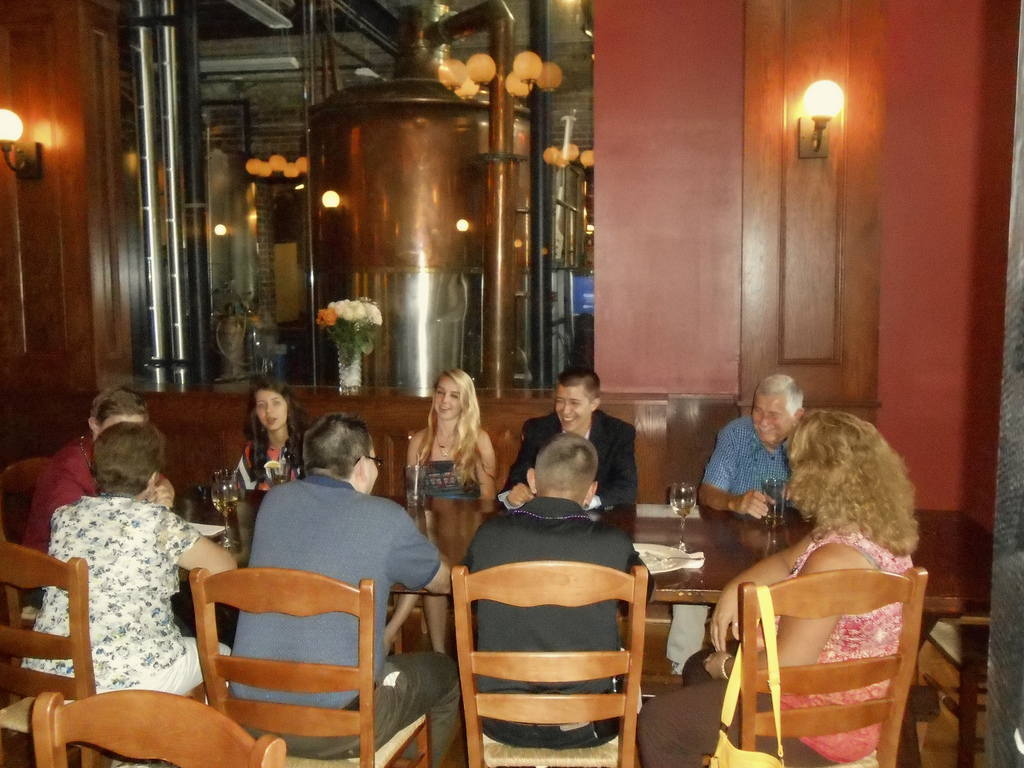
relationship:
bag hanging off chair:
[708, 584, 785, 768] [721, 541, 934, 761]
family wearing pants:
[228, 413, 459, 767] [238, 639, 457, 764]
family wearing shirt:
[228, 413, 459, 767] [229, 467, 445, 718]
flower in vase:
[358, 302, 384, 331] [336, 345, 365, 393]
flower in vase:
[316, 307, 338, 325] [336, 345, 365, 393]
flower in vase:
[339, 300, 365, 330] [336, 345, 365, 393]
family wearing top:
[637, 408, 921, 768] [770, 525, 927, 757]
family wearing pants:
[637, 408, 921, 768] [633, 679, 817, 765]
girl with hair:
[383, 369, 496, 657] [408, 366, 479, 499]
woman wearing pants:
[21, 421, 238, 706] [131, 635, 227, 706]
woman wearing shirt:
[21, 421, 238, 706] [26, 495, 195, 686]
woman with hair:
[222, 381, 325, 506] [244, 381, 306, 476]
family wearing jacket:
[458, 432, 657, 750] [458, 496, 655, 696]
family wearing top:
[637, 408, 921, 768] [772, 524, 913, 758]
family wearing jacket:
[496, 366, 639, 511] [509, 407, 636, 506]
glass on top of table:
[669, 483, 701, 548] [21, 506, 999, 759]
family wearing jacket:
[458, 432, 657, 750] [453, 495, 651, 704]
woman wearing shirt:
[24, 411, 240, 702] [38, 490, 201, 697]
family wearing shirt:
[666, 374, 804, 675] [708, 414, 795, 504]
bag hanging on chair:
[713, 577, 786, 767] [740, 568, 933, 761]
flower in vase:
[315, 306, 341, 330] [329, 331, 365, 401]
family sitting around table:
[231, 410, 479, 766] [21, 506, 999, 759]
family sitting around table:
[456, 435, 665, 746] [21, 506, 999, 759]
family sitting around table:
[501, 367, 639, 511] [21, 506, 999, 759]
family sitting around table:
[699, 367, 808, 517] [21, 506, 999, 759]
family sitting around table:
[702, 400, 914, 743] [21, 506, 999, 759]